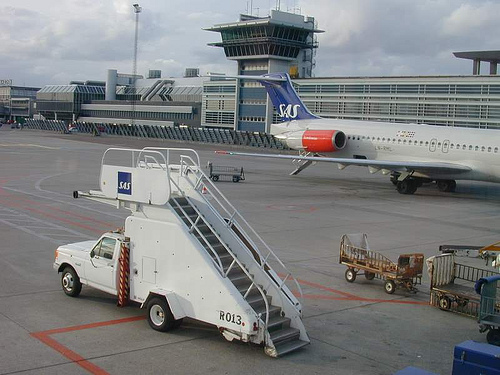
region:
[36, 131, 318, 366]
Tall white and blue truck with stairs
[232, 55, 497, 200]
White and blue airplane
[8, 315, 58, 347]
Small part of painted concrete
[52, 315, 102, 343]
Small part of painted concrete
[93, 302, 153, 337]
Small part of painted concrete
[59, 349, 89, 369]
Small part of painted concrete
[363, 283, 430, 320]
Small part of painted concrete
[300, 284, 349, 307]
Small part of painted concrete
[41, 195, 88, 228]
Small part of painted concrete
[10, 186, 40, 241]
Small part of painted concrete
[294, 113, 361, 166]
back part of the plane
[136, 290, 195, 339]
back wheel of the van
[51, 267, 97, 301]
front wheel of the van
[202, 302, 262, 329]
a text written in van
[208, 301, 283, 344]
name of the van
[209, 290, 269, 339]
number of the van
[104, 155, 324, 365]
a steps holder in van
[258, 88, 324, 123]
logo display in plane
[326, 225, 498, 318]
a laguage holder trolly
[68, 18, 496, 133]
a very large air port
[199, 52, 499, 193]
an airplane in an airport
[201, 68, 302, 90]
horizontal fins on vertical stabilizer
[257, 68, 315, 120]
vertical stabilizer of plane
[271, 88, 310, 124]
white letters on stabilizer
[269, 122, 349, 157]
a gray and red engine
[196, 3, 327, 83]
the tower of an airport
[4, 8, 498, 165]
the building of an airport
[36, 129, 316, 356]
a car is carrying the stairs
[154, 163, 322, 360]
a mobile stairs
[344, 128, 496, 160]
the windows for passengers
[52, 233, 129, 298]
the white truck front cab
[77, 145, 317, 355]
the moveable staircase on a truck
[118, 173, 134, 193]
the white and blue SAS logo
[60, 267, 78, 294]
the black rubber wheel of the truck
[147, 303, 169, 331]
the black rubber wheel of the truck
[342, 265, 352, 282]
the black rubber wheel of the luggage car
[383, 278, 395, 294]
the black rubber wheel of the luggage car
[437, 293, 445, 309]
the black rubber wheel of the luggage car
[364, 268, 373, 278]
the black rubber wheel of the luggage car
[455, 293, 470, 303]
the black rubber wheel of the luggage car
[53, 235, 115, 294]
the front of a truck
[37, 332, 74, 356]
red line in the street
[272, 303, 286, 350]
stairs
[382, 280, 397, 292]
wheels on the cart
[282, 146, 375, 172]
the wing of an airplane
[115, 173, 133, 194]
blue logo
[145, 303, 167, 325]
a tire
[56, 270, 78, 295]
front tire on the truck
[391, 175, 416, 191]
a wheel on the airplane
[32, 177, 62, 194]
a white line on the roadway